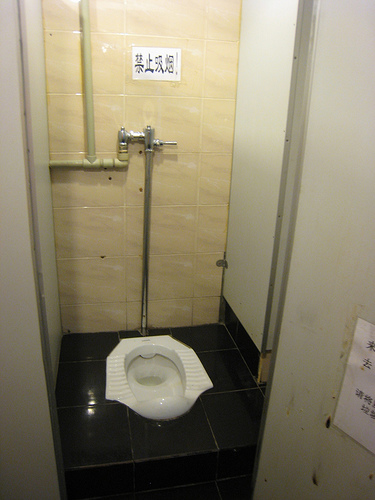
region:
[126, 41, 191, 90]
sign on the wall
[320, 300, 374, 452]
sign on the wall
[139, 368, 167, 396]
water in the toliet bowl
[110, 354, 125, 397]
part of the seat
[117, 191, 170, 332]
silver piping in back of the toliet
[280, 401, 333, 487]
dirty markings on the wall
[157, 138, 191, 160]
silver handle to flush toliet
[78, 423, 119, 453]
black floor that toliet is in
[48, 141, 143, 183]
piping connected to the toliet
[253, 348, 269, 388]
tag on the piping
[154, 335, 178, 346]
part of the seat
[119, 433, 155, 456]
black flooring for the toliet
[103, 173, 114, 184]
spot on the wall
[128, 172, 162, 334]
pipe on the wall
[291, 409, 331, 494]
dirty marks on the wall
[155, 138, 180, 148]
handle to flush toliet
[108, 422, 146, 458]
line in the floor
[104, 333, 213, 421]
squat toilet in the floor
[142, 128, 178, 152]
flush handle of the toilet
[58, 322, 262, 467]
black tile floor in the toilet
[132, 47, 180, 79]
sign in an asian language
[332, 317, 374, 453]
sign in an asian language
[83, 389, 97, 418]
reflection on the floor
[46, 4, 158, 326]
exposed plumbing to the toilet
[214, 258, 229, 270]
bracket to connect the walls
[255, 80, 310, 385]
sliding door of the room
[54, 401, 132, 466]
a piece of black tile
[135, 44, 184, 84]
white sign on wall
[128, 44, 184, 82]
white sign with black letters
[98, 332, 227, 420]
white toilet on black platform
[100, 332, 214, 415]
toilet seat is down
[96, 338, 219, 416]
toilet seat has ridges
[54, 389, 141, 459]
black tiles beneath toilet seat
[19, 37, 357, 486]
stall in a restroom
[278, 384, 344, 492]
rust marks on door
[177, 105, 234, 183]
yellow tiles on wall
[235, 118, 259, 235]
wall painted white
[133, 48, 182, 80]
black lettering on a white sign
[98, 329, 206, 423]
a white porcelain toilet in the ground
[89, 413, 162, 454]
black stone tiles of the floor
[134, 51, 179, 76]
chinese characters on the sign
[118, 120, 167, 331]
chrome metal pipe for the toilet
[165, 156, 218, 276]
white stone tiles of the wall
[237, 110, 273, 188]
white surface of the walls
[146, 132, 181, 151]
chrome metal lever for the toilet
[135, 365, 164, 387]
clear water in the toilet bowl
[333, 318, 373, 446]
a white paper sign on the door